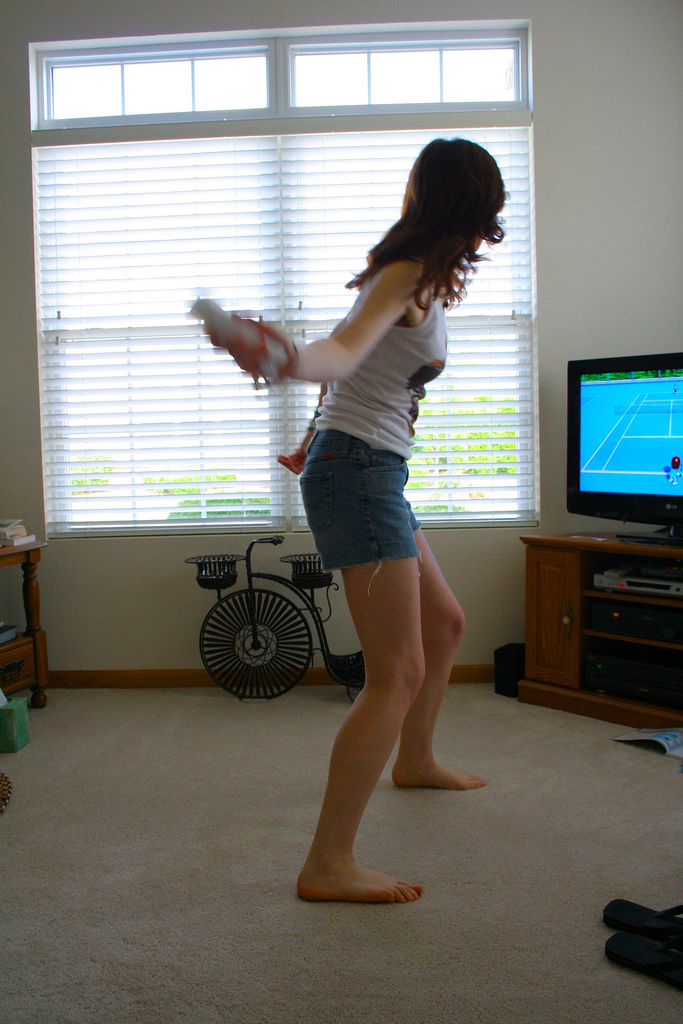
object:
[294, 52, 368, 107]
window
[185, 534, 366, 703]
stand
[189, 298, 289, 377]
remote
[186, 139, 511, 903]
lady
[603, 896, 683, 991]
slippers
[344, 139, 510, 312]
hair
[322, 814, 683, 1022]
road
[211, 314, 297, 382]
hand